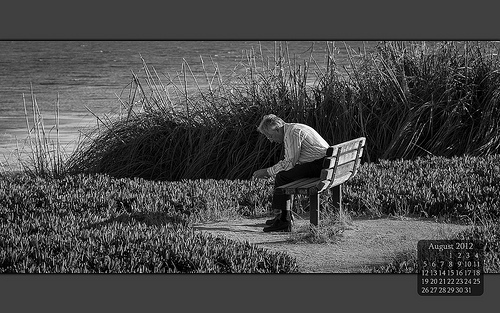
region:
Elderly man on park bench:
[231, 95, 333, 225]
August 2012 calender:
[416, 227, 498, 292]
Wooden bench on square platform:
[276, 159, 363, 224]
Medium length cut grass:
[28, 169, 487, 279]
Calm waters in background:
[3, 25, 489, 167]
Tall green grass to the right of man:
[103, 39, 498, 221]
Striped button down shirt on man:
[285, 125, 328, 168]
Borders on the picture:
[1, 2, 498, 77]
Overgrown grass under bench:
[295, 218, 362, 242]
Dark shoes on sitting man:
[253, 209, 300, 231]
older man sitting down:
[236, 96, 363, 242]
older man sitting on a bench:
[237, 106, 374, 244]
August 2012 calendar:
[407, 231, 498, 303]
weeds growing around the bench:
[293, 211, 356, 243]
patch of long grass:
[55, 42, 497, 169]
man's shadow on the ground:
[83, 205, 274, 242]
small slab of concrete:
[199, 203, 466, 282]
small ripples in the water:
[16, 48, 114, 95]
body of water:
[2, 40, 496, 167]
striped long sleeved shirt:
[261, 122, 327, 177]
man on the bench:
[239, 78, 363, 208]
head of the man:
[250, 113, 285, 150]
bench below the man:
[288, 141, 378, 213]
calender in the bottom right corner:
[376, 226, 498, 294]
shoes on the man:
[246, 206, 296, 245]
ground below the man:
[214, 210, 259, 247]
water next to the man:
[38, 51, 119, 114]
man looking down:
[221, 51, 363, 241]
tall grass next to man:
[165, 75, 252, 152]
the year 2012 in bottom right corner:
[449, 225, 484, 258]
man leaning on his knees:
[239, 101, 325, 244]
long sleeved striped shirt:
[268, 121, 327, 180]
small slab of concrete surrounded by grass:
[186, 199, 438, 284]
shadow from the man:
[89, 203, 259, 239]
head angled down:
[253, 108, 290, 150]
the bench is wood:
[274, 134, 372, 193]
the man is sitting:
[260, 100, 375, 239]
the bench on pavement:
[290, 131, 380, 256]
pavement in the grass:
[186, 191, 421, 265]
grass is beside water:
[12, 47, 120, 222]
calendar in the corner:
[383, 195, 497, 311]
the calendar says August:
[412, 217, 497, 310]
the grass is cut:
[38, 198, 178, 270]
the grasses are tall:
[291, 39, 492, 164]